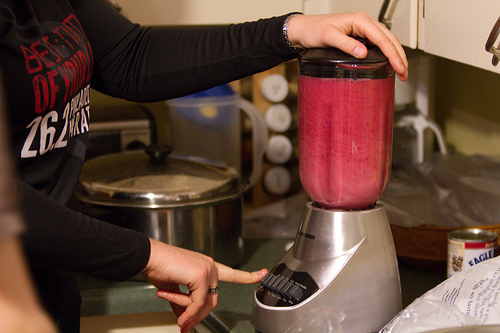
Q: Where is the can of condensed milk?
A: To the right of the blender.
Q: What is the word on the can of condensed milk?
A: Eagle.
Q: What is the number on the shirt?
A: 262.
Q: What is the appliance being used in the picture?
A: A blender.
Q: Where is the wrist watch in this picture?
A: On the left hand.